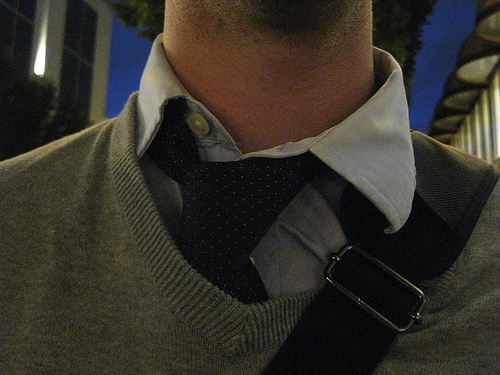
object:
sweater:
[0, 88, 499, 375]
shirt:
[137, 30, 420, 300]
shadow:
[237, 0, 368, 50]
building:
[0, 1, 500, 171]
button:
[187, 110, 210, 134]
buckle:
[324, 243, 426, 333]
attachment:
[323, 244, 431, 331]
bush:
[33, 73, 55, 144]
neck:
[163, 0, 373, 152]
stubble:
[259, 3, 353, 50]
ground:
[378, 172, 400, 207]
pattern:
[152, 102, 319, 305]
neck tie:
[142, 106, 326, 302]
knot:
[171, 157, 326, 270]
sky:
[105, 14, 151, 122]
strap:
[259, 155, 500, 375]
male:
[0, 0, 500, 375]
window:
[0, 0, 96, 166]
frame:
[0, 0, 100, 161]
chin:
[268, 3, 340, 12]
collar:
[135, 31, 416, 235]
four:
[14, 50, 104, 120]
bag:
[257, 163, 500, 375]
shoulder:
[0, 117, 105, 261]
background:
[0, 0, 500, 172]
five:
[52, 42, 108, 145]